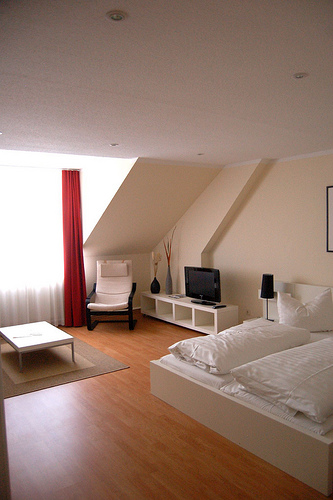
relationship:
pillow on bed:
[168, 319, 311, 374] [151, 281, 330, 497]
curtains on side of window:
[63, 170, 88, 326] [1, 166, 67, 294]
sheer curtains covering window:
[1, 171, 64, 325] [1, 166, 67, 294]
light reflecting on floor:
[5, 385, 81, 440] [1, 309, 321, 499]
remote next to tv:
[215, 303, 225, 310] [184, 266, 220, 305]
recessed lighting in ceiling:
[109, 9, 130, 22] [2, 1, 332, 155]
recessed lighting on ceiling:
[293, 74, 307, 82] [2, 1, 332, 155]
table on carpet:
[0, 321, 75, 368] [2, 337, 127, 399]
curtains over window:
[63, 170, 88, 326] [1, 166, 67, 294]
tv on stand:
[184, 266, 220, 305] [140, 289, 238, 335]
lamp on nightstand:
[258, 273, 274, 322] [243, 315, 278, 324]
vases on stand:
[151, 272, 174, 295] [140, 289, 238, 335]